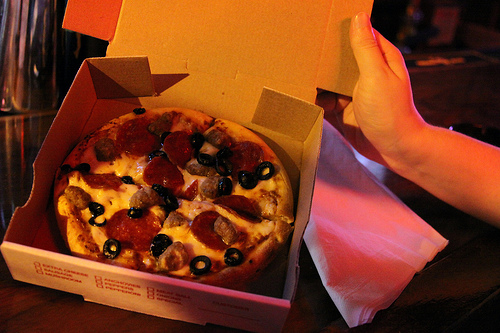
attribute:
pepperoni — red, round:
[126, 124, 142, 144]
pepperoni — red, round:
[169, 142, 175, 149]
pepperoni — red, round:
[241, 147, 252, 159]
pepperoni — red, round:
[158, 173, 168, 179]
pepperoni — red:
[189, 190, 194, 195]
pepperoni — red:
[239, 202, 244, 203]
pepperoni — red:
[94, 179, 102, 184]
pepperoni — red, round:
[205, 223, 209, 233]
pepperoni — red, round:
[121, 227, 138, 237]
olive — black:
[134, 107, 146, 113]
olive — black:
[162, 133, 167, 138]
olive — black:
[195, 135, 197, 144]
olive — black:
[198, 156, 206, 162]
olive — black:
[219, 164, 223, 171]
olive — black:
[220, 153, 224, 154]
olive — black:
[247, 174, 252, 184]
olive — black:
[263, 164, 273, 169]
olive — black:
[224, 181, 229, 190]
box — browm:
[160, 13, 280, 78]